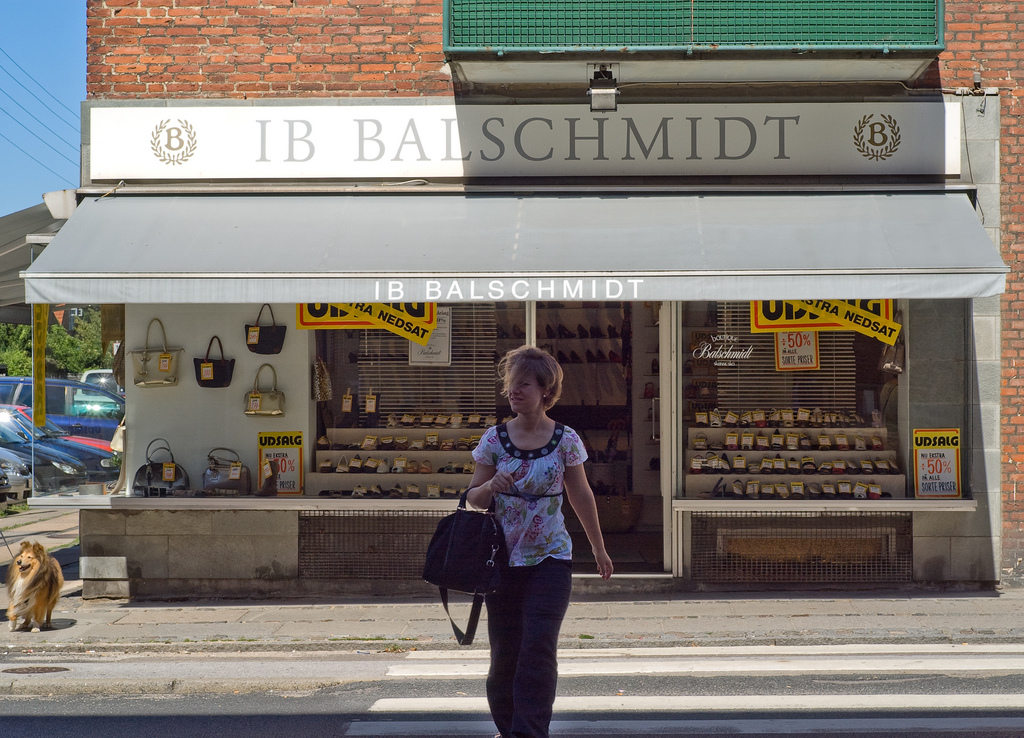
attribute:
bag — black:
[424, 512, 505, 599]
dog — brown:
[10, 533, 80, 631]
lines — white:
[681, 676, 770, 729]